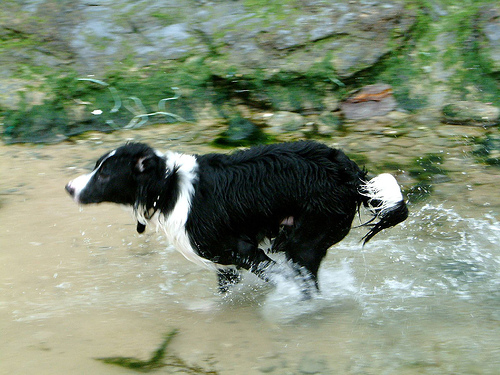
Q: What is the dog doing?
A: Running through water.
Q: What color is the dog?
A: Black and white.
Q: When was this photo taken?
A: During the day.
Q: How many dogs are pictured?
A: Just 1.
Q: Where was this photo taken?
A: By the water.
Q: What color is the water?
A: It is brown.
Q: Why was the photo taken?
A: To show the dog in action.